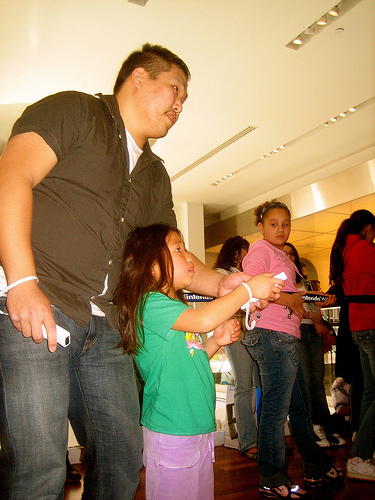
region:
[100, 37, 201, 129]
head of a person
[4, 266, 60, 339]
hand of a person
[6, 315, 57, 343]
fingers of a person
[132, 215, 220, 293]
head of a person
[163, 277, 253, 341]
arm of a person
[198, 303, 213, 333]
elbow of a person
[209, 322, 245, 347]
hand of a person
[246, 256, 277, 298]
hand of a person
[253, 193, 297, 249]
head of a person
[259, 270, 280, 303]
fingers of a person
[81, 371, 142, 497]
the man is wearing pants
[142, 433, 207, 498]
the girl has purple pants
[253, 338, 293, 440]
the girl is wearing jeans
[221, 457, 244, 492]
the floor is wooden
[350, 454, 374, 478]
white shoe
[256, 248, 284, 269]
a pink sweatshirt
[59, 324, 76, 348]
a wii controller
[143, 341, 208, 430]
the girl is wearing a green shirt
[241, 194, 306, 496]
this is a person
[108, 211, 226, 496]
this is a person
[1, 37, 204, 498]
this is a person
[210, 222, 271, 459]
this is a person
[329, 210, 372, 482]
this is a person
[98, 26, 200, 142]
the head of a person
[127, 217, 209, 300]
the head of a person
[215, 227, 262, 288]
the head of a person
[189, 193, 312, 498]
this is a person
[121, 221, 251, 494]
this is a person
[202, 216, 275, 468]
this is a person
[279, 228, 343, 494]
this is a person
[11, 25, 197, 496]
this is a person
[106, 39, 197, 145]
the head of a person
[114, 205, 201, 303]
the head of a person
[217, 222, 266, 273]
the head of a person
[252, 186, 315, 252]
the head of a person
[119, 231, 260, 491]
A person with a remote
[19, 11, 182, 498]
A person with a remote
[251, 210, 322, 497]
A person with a remote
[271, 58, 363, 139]
A white building ceilling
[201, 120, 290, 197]
A white building ceilling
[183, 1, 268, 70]
A white building ceilling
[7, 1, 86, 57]
A white building ceilling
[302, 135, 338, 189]
A white building ceilling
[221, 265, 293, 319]
girl holding a Wii controller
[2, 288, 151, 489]
man wearing blue jeans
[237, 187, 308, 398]
a person standing inside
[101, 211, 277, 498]
a person standing inside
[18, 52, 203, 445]
a person standing inside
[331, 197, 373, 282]
a person standing inside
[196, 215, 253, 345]
a person standing inside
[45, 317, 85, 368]
a white wii remote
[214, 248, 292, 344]
a white wii remote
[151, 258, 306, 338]
a girl holding a wii remote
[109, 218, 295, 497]
a girl wearing a green shirt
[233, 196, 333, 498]
a girl wearing a pink shirt